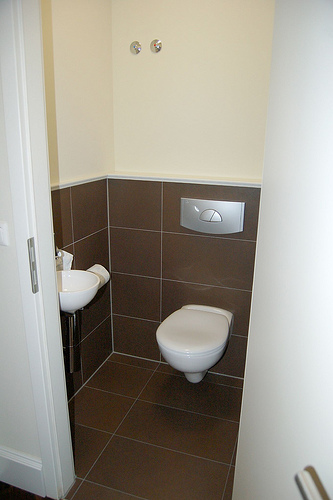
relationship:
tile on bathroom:
[49, 177, 262, 498] [1, 4, 321, 497]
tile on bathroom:
[49, 177, 262, 498] [28, 21, 329, 493]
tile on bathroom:
[49, 177, 262, 498] [39, 7, 294, 491]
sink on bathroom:
[53, 262, 94, 303] [41, 28, 260, 419]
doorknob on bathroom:
[295, 465, 331, 498] [39, 7, 294, 491]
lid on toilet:
[155, 306, 232, 351] [158, 301, 236, 383]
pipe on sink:
[69, 312, 77, 374] [51, 257, 101, 315]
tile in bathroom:
[49, 177, 262, 498] [39, 7, 294, 491]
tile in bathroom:
[108, 228, 161, 281] [39, 7, 294, 491]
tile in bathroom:
[49, 177, 262, 498] [1, 4, 321, 497]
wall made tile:
[107, 0, 275, 379] [105, 174, 177, 251]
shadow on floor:
[159, 369, 236, 438] [0, 352, 243, 499]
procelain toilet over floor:
[156, 303, 235, 383] [82, 378, 232, 499]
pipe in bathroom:
[61, 314, 83, 377] [25, 5, 265, 497]